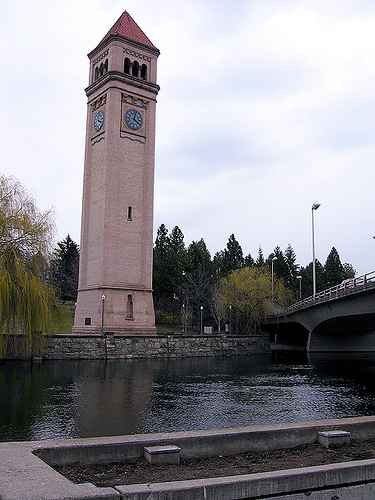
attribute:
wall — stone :
[3, 438, 62, 491]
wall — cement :
[2, 439, 81, 492]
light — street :
[308, 201, 322, 291]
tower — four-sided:
[77, 6, 161, 329]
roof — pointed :
[94, 8, 160, 46]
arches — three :
[121, 55, 150, 78]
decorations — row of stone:
[119, 89, 152, 110]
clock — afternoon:
[86, 104, 145, 138]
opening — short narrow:
[125, 199, 135, 224]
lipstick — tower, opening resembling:
[121, 290, 135, 328]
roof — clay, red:
[87, 9, 159, 58]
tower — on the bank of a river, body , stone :
[65, 8, 165, 338]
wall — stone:
[1, 331, 273, 358]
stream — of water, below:
[42, 357, 319, 414]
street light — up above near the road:
[307, 196, 328, 296]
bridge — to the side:
[267, 300, 363, 357]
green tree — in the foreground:
[0, 174, 64, 358]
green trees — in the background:
[151, 220, 251, 324]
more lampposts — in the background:
[178, 300, 236, 332]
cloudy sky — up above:
[205, 47, 334, 158]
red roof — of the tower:
[121, 16, 134, 37]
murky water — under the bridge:
[3, 360, 308, 418]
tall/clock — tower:
[72, 7, 165, 339]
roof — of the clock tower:
[88, 7, 160, 52]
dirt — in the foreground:
[61, 456, 274, 481]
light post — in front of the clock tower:
[98, 289, 108, 329]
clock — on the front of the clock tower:
[122, 104, 144, 131]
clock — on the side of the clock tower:
[91, 109, 105, 134]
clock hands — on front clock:
[132, 113, 142, 127]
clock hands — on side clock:
[93, 113, 103, 125]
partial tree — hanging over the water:
[0, 167, 62, 366]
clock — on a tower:
[123, 105, 143, 132]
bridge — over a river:
[264, 277, 362, 358]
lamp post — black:
[101, 289, 104, 331]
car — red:
[337, 276, 372, 291]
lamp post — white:
[310, 201, 323, 295]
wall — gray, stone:
[0, 335, 270, 360]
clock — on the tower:
[123, 107, 144, 130]